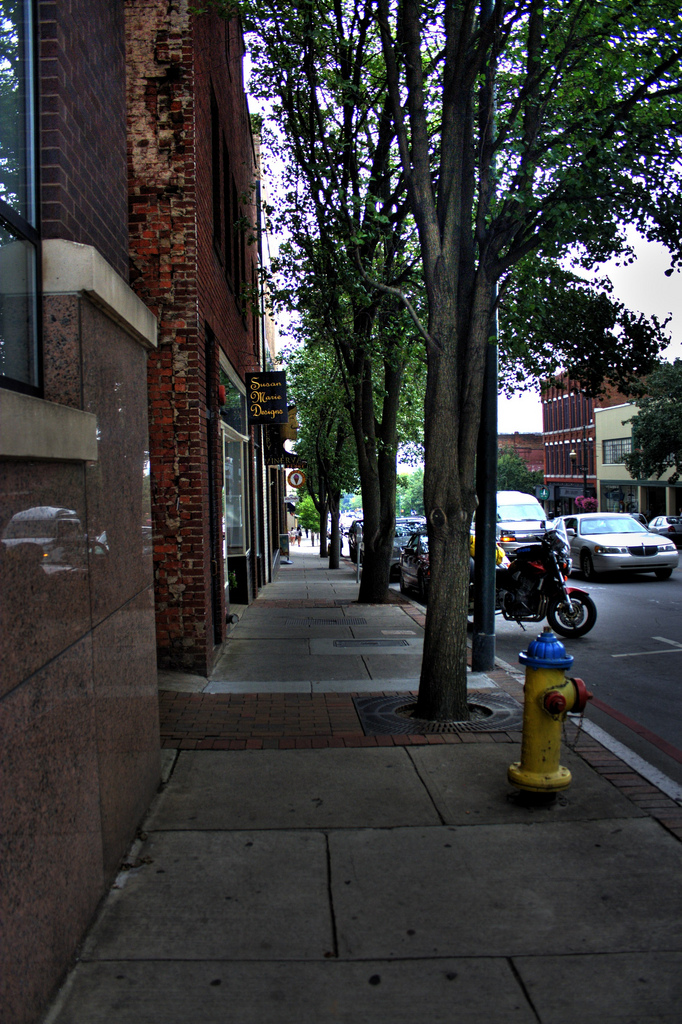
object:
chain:
[564, 709, 581, 744]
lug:
[544, 692, 565, 719]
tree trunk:
[420, 337, 468, 717]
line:
[588, 696, 677, 775]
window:
[2, 2, 41, 393]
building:
[0, 0, 159, 1022]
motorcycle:
[488, 523, 596, 636]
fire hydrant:
[507, 629, 590, 810]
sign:
[287, 473, 301, 487]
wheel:
[547, 591, 596, 641]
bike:
[488, 532, 597, 633]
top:
[520, 625, 574, 666]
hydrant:
[504, 625, 593, 806]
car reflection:
[27, 536, 111, 596]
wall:
[0, 462, 159, 1020]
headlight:
[602, 545, 619, 553]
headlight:
[661, 547, 669, 550]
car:
[553, 514, 677, 582]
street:
[568, 547, 678, 797]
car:
[647, 515, 678, 542]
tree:
[241, 0, 681, 723]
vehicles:
[651, 514, 681, 542]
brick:
[175, 510, 195, 530]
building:
[153, 5, 284, 626]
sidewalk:
[55, 529, 663, 1021]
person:
[295, 525, 302, 547]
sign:
[241, 370, 286, 422]